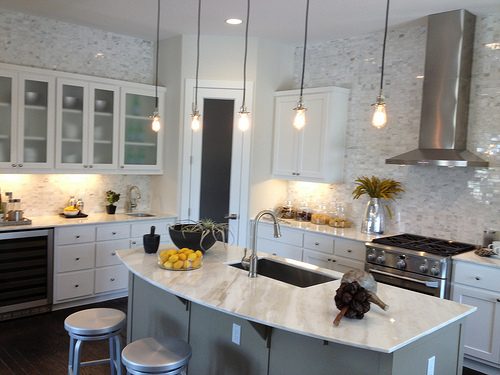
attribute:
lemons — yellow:
[157, 246, 202, 270]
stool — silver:
[63, 306, 126, 373]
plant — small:
[166, 217, 236, 250]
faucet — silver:
[241, 210, 282, 277]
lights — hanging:
[150, 0, 391, 133]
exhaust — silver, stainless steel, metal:
[386, 8, 489, 166]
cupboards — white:
[0, 61, 352, 184]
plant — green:
[352, 174, 404, 220]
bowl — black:
[142, 233, 160, 253]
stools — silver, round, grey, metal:
[64, 306, 193, 373]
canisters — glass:
[276, 195, 350, 229]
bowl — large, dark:
[168, 222, 222, 253]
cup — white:
[488, 240, 500, 253]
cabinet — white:
[271, 86, 351, 186]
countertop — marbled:
[250, 213, 500, 268]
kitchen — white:
[0, 0, 499, 374]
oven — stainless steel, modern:
[365, 232, 480, 300]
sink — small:
[128, 212, 156, 220]